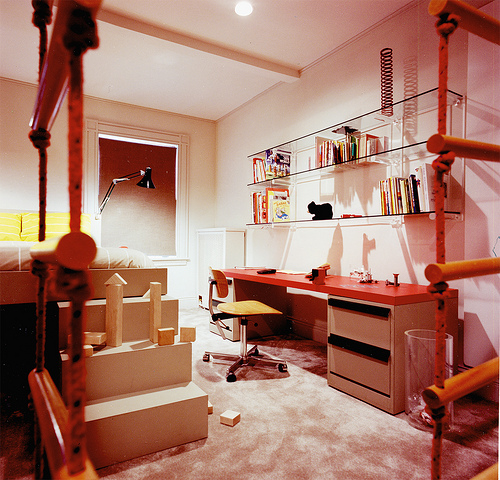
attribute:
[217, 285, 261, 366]
chair — back, small, wood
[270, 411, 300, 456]
carpet — clean, brown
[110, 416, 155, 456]
block — wood, grouped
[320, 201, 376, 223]
shelf — glass, clear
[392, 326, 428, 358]
dust bin — glass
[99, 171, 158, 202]
lamp — office, black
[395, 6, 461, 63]
bar — wood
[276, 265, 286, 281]
surface — red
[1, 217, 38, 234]
pillow — yellow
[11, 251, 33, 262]
mattress — brown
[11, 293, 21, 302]
cabinet — brown